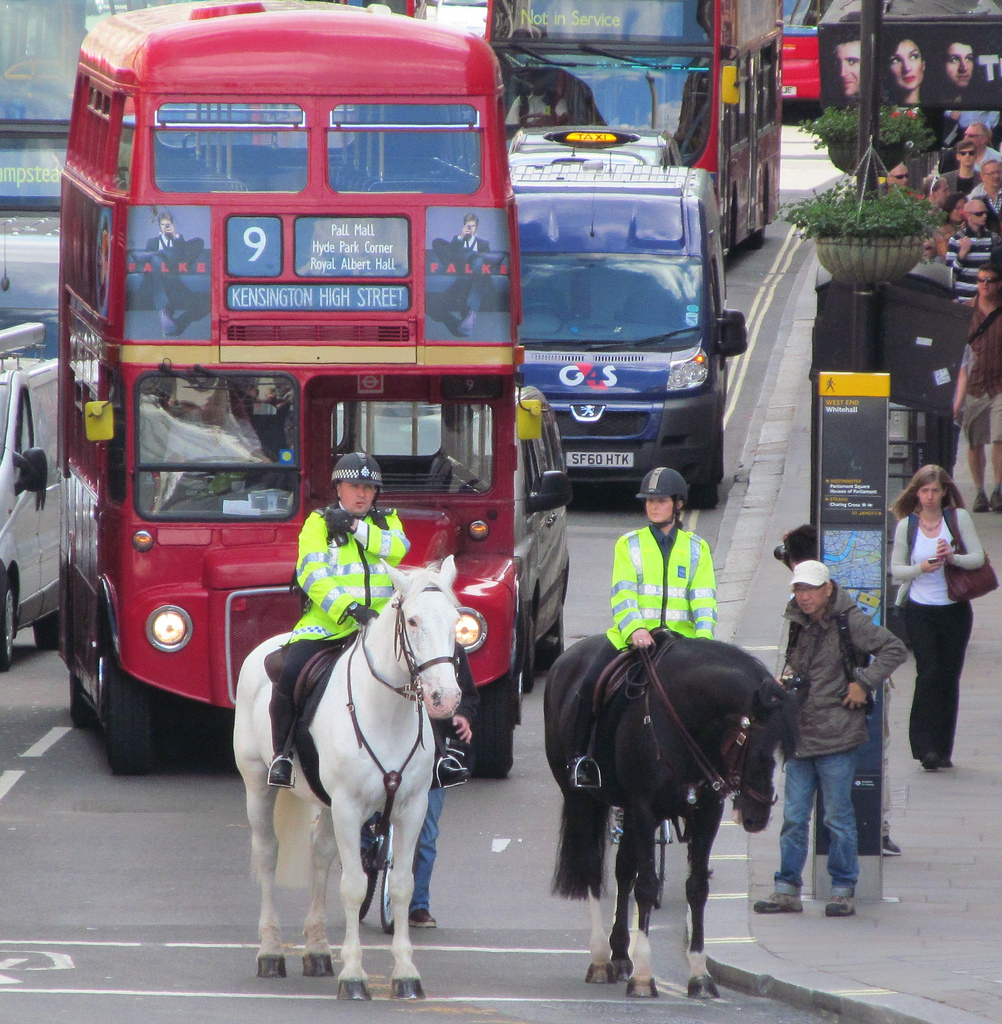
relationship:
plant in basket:
[784, 190, 957, 242] [810, 234, 930, 292]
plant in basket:
[785, 191, 931, 243] [826, 134, 902, 174]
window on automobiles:
[150, 95, 313, 195] [61, 9, 520, 770]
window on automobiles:
[322, 101, 484, 193] [61, 9, 520, 770]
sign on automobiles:
[216, 205, 416, 317] [61, 9, 520, 770]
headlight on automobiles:
[147, 602, 194, 653] [61, 9, 520, 770]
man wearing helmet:
[267, 454, 412, 791] [331, 451, 385, 491]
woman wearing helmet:
[566, 458, 722, 785] [633, 462, 685, 505]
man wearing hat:
[753, 558, 907, 915] [783, 558, 837, 592]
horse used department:
[227, 559, 462, 1006] [337, 460, 378, 478]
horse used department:
[227, 559, 462, 1006] [341, 460, 382, 481]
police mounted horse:
[257, 442, 723, 804] [227, 559, 462, 1006]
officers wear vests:
[264, 439, 732, 803] [290, 501, 723, 657]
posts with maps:
[782, 296, 913, 871] [822, 528, 885, 631]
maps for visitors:
[822, 528, 885, 631] [758, 550, 889, 932]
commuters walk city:
[740, 479, 971, 932] [11, 14, 961, 1016]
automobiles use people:
[18, 10, 710, 793] [904, 65, 971, 582]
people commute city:
[904, 65, 971, 582] [84, 74, 953, 955]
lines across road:
[0, 721, 61, 835] [13, 774, 198, 934]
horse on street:
[538, 623, 794, 1011] [15, 759, 215, 997]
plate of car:
[565, 440, 656, 476] [507, 107, 747, 518]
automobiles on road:
[61, 9, 520, 770] [12, 774, 656, 1016]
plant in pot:
[785, 191, 931, 243] [782, 136, 933, 289]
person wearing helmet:
[561, 459, 755, 837] [632, 457, 703, 517]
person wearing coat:
[561, 458, 751, 785] [598, 515, 740, 646]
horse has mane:
[227, 559, 462, 1006] [379, 548, 440, 617]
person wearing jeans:
[764, 559, 898, 930] [769, 765, 874, 907]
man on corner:
[781, 535, 888, 921] [735, 521, 897, 940]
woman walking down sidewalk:
[886, 461, 980, 770] [699, 231, 992, 1014]